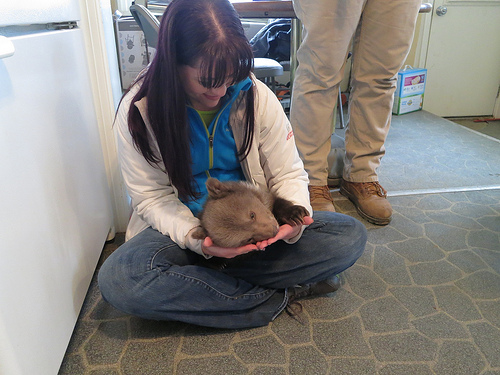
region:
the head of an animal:
[184, 172, 284, 248]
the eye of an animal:
[243, 206, 261, 223]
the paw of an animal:
[279, 199, 312, 231]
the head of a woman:
[150, 0, 255, 114]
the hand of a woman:
[198, 234, 258, 259]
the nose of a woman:
[211, 77, 229, 98]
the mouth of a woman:
[201, 87, 228, 105]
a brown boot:
[333, 168, 396, 227]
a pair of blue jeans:
[91, 205, 368, 332]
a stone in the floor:
[356, 289, 413, 334]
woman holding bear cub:
[95, 0, 367, 332]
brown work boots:
[305, 178, 396, 229]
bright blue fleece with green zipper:
[181, 78, 252, 211]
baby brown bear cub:
[188, 178, 307, 252]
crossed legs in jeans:
[94, 211, 368, 333]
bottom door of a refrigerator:
[0, 26, 112, 374]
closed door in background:
[416, 0, 498, 117]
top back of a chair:
[127, 3, 162, 50]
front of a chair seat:
[249, 55, 284, 75]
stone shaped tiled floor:
[59, 190, 499, 374]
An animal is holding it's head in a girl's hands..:
[156, 148, 332, 265]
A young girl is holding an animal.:
[75, 1, 407, 341]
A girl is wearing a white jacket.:
[91, 38, 336, 274]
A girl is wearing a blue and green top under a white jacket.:
[142, 66, 269, 221]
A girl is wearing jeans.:
[88, 197, 381, 336]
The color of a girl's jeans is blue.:
[80, 181, 385, 356]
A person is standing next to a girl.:
[257, 1, 443, 238]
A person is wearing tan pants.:
[275, 1, 452, 211]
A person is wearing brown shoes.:
[280, 165, 409, 232]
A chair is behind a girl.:
[100, 0, 292, 127]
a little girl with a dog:
[91, 3, 373, 321]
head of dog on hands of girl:
[136, 175, 322, 256]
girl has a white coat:
[77, 1, 382, 346]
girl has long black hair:
[115, 0, 276, 201]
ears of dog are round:
[175, 165, 231, 250]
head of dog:
[173, 173, 323, 273]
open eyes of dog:
[234, 203, 266, 255]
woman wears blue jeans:
[79, 4, 378, 344]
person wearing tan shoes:
[288, 4, 427, 231]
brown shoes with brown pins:
[302, 174, 405, 236]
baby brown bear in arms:
[168, 178, 300, 240]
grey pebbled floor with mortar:
[351, 296, 413, 333]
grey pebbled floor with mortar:
[429, 335, 485, 372]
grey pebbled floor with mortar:
[378, 233, 439, 263]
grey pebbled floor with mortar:
[221, 334, 293, 364]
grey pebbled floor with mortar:
[175, 350, 245, 372]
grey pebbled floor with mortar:
[423, 218, 472, 254]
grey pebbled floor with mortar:
[428, 283, 474, 327]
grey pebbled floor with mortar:
[439, 247, 486, 277]